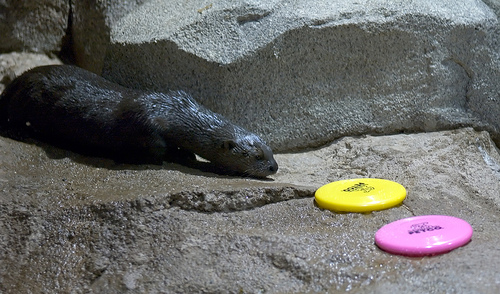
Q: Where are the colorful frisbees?
A: On the beach.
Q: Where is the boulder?
A: Behind the frisbees.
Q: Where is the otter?
A: Examining the frisbees.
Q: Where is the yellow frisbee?
A: Between the otter and the pink frisbee.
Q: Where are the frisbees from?
A: Petco.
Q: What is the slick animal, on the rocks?
A: An otter.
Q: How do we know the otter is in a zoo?
A: The habitat is man-made.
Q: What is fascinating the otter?
A: Two plastic discs.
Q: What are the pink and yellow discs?
A: Frisbees.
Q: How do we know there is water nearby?
A: The otter and the rock are both wet.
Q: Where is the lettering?
A: On the back of the Frisbees.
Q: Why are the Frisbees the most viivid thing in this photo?
A: Because the rock and the otter are both neutrally colored.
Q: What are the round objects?
A: Frisbees.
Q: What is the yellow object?
A: A frisbee.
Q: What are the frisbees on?
A: A rock.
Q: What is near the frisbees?
A: A seal.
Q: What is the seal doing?
A: Looking at the frisbees.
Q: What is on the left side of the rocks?
A: A seal.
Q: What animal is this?
A: Otter.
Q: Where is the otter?
A: On the rock.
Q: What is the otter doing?
A: Lying down.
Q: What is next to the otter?
A: Frisbee toys.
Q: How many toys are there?
A: Two.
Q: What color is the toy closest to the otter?
A: Yellow.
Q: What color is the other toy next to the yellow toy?
A: Pink.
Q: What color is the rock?
A: Grey.